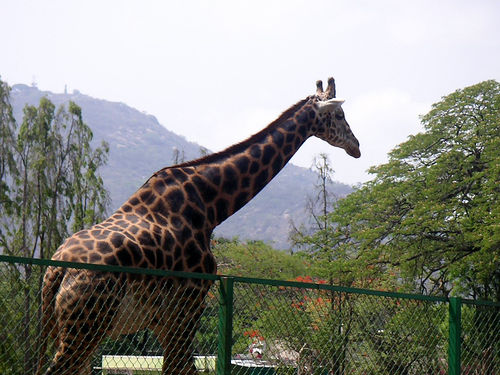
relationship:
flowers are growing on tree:
[296, 262, 346, 316] [294, 262, 370, 365]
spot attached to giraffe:
[162, 180, 194, 220] [37, 55, 364, 373]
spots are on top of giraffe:
[119, 201, 194, 261] [53, 68, 363, 330]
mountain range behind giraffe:
[49, 63, 204, 210] [91, 65, 400, 360]